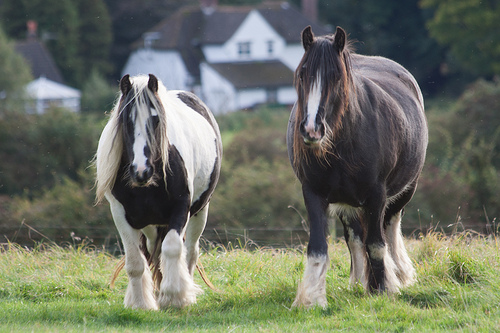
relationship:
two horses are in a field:
[87, 25, 429, 314] [3, 96, 500, 332]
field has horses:
[3, 96, 500, 332] [87, 25, 429, 314]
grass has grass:
[1, 224, 500, 333] [1, 224, 498, 329]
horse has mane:
[287, 25, 429, 311] [291, 35, 356, 176]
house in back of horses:
[121, 4, 341, 115] [87, 25, 429, 314]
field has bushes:
[3, 96, 500, 332] [4, 49, 499, 215]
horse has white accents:
[287, 25, 429, 311] [303, 71, 322, 131]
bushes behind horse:
[0, 76, 498, 247] [287, 25, 429, 311]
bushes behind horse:
[0, 76, 498, 247] [84, 72, 223, 310]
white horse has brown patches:
[84, 72, 223, 310] [111, 80, 195, 230]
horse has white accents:
[287, 25, 429, 311] [291, 71, 421, 312]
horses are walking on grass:
[87, 25, 429, 314] [1, 224, 498, 329]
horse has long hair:
[287, 25, 429, 311] [291, 35, 356, 176]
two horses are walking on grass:
[87, 25, 429, 314] [1, 224, 498, 329]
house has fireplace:
[121, 4, 341, 115] [301, 0, 318, 28]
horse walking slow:
[287, 25, 429, 311] [287, 181, 417, 317]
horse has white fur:
[287, 25, 429, 311] [290, 208, 417, 313]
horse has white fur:
[84, 72, 223, 310] [90, 73, 215, 313]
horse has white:
[84, 72, 223, 310] [95, 74, 202, 316]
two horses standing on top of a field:
[87, 25, 429, 314] [3, 96, 500, 332]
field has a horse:
[3, 96, 500, 332] [287, 25, 429, 311]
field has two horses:
[3, 96, 500, 332] [87, 25, 429, 314]